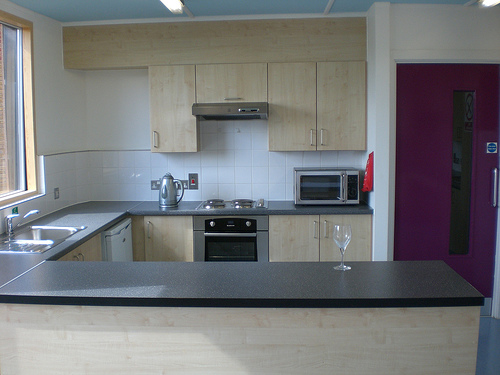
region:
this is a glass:
[328, 219, 368, 276]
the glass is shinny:
[328, 223, 351, 255]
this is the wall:
[66, 72, 139, 139]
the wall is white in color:
[72, 77, 122, 130]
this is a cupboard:
[253, 10, 348, 129]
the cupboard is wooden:
[283, 52, 340, 122]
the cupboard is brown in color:
[268, 77, 339, 135]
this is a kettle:
[156, 168, 188, 203]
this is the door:
[403, 61, 475, 244]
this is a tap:
[11, 212, 33, 233]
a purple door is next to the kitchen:
[393, 63, 499, 241]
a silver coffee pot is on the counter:
[154, 173, 185, 206]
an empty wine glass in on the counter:
[326, 219, 356, 270]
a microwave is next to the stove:
[287, 163, 362, 209]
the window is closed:
[7, 16, 40, 204]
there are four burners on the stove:
[207, 192, 251, 219]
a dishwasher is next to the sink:
[100, 216, 144, 248]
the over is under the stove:
[197, 210, 262, 267]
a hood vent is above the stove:
[182, 88, 272, 123]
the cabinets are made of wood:
[279, 75, 342, 130]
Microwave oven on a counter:
[292, 168, 362, 205]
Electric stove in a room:
[192, 195, 271, 260]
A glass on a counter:
[329, 223, 354, 270]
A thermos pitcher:
[156, 175, 185, 210]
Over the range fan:
[192, 101, 270, 119]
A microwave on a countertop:
[292, 165, 362, 209]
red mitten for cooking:
[360, 152, 377, 193]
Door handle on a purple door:
[490, 168, 498, 211]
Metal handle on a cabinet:
[311, 219, 318, 239]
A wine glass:
[328, 224, 353, 271]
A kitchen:
[8, 5, 488, 374]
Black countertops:
[0, 194, 490, 307]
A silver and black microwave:
[290, 165, 365, 213]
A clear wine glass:
[331, 224, 354, 269]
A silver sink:
[3, 205, 89, 267]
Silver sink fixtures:
[4, 203, 55, 243]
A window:
[4, 11, 46, 208]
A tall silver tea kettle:
[152, 172, 188, 210]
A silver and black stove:
[196, 194, 271, 259]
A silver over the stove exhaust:
[195, 101, 272, 118]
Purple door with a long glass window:
[395, 62, 497, 295]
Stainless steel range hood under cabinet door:
[192, 64, 268, 121]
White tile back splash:
[0, 150, 94, 233]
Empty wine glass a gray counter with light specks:
[3, 223, 484, 306]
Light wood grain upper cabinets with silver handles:
[67, 18, 367, 151]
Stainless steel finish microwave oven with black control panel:
[291, 165, 363, 206]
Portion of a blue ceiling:
[4, 0, 371, 17]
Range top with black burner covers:
[195, 195, 268, 212]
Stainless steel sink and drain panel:
[0, 223, 87, 251]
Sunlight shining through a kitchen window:
[3, 25, 123, 243]